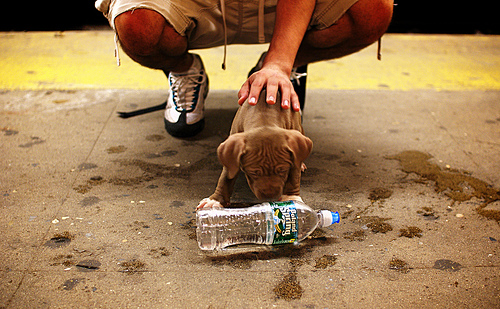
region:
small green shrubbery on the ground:
[358, 185, 440, 263]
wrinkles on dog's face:
[237, 137, 306, 184]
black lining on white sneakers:
[158, 99, 213, 143]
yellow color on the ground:
[401, 50, 470, 85]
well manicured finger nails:
[235, 90, 317, 122]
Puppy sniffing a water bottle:
[197, 74, 340, 261]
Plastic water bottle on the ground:
[196, 200, 341, 254]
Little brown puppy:
[203, 87, 310, 209]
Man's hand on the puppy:
[239, 50, 304, 113]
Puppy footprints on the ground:
[130, 194, 170, 263]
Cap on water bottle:
[320, 207, 338, 228]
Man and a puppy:
[104, 0, 409, 209]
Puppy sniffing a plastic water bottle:
[198, 91, 340, 255]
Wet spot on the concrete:
[378, 125, 493, 222]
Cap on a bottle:
[330, 205, 343, 227]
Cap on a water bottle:
[328, 207, 344, 226]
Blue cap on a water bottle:
[331, 208, 343, 224]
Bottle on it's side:
[191, 202, 342, 257]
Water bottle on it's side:
[192, 200, 345, 260]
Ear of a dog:
[209, 133, 245, 186]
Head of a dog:
[216, 128, 316, 199]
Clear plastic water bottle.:
[187, 194, 354, 254]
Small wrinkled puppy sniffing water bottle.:
[192, 71, 324, 212]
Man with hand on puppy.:
[197, 15, 337, 215]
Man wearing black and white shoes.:
[130, 52, 361, 138]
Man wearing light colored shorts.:
[77, 0, 401, 82]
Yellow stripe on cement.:
[1, 18, 493, 106]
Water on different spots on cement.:
[114, 95, 490, 280]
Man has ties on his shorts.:
[146, 8, 323, 81]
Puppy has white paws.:
[192, 175, 323, 234]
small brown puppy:
[222, 74, 325, 197]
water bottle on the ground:
[192, 195, 336, 250]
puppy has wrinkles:
[208, 75, 323, 197]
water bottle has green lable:
[185, 188, 345, 262]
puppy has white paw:
[192, 83, 311, 218]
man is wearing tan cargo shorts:
[103, 3, 404, 136]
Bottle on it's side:
[201, 183, 346, 254]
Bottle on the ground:
[199, 197, 348, 257]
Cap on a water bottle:
[330, 201, 345, 230]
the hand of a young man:
[235, 61, 302, 115]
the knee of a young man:
[108, 15, 175, 56]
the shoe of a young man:
[145, 36, 215, 150]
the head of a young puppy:
[212, 128, 312, 199]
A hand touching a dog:
[211, 71, 322, 174]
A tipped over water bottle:
[191, 199, 354, 251]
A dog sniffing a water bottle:
[215, 121, 330, 251]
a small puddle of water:
[382, 141, 496, 210]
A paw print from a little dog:
[147, 242, 172, 264]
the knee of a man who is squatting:
[103, 5, 169, 65]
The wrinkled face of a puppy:
[214, 123, 318, 204]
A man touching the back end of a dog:
[103, 1, 324, 199]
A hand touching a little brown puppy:
[214, 65, 319, 200]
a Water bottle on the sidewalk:
[186, 203, 353, 260]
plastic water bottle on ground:
[193, 200, 342, 251]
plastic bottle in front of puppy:
[199, 201, 340, 249]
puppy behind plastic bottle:
[197, 81, 314, 213]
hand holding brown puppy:
[237, 64, 304, 112]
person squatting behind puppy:
[93, 0, 394, 142]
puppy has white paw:
[196, 196, 222, 212]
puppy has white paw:
[281, 193, 305, 203]